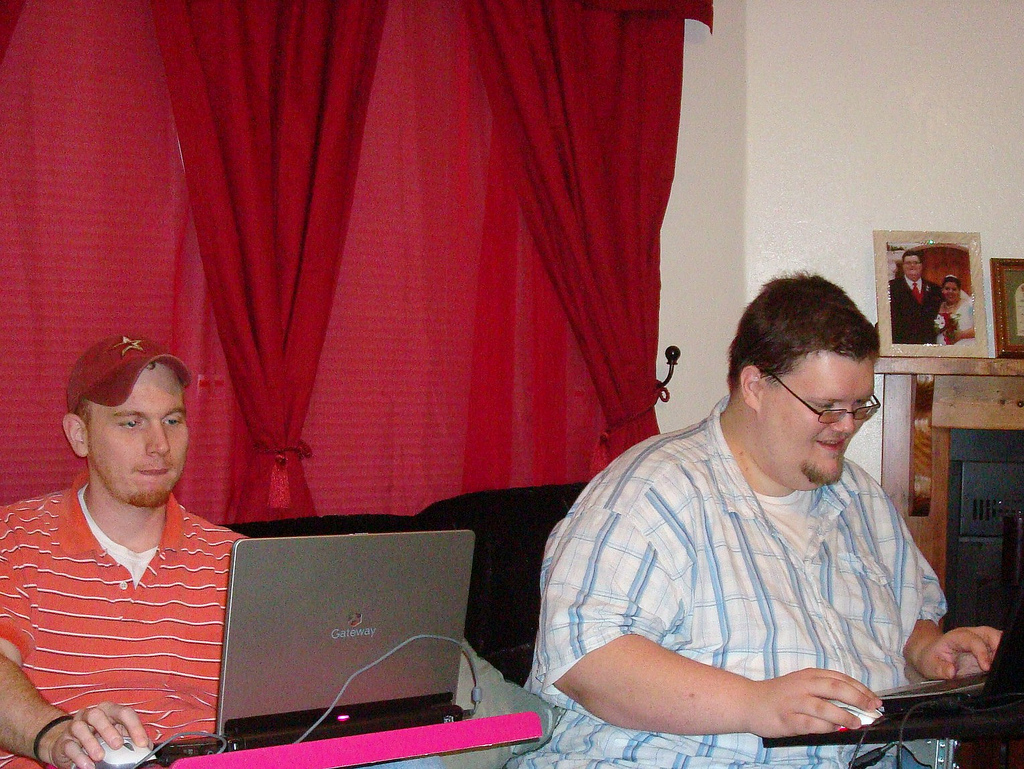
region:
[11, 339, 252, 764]
man is clicking his mouse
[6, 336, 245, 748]
man wearing orange shirt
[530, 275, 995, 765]
man wearing white and blue shirt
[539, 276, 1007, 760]
man typing on keyboard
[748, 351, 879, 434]
glasses are black in color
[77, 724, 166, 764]
laptop mouse is white and gray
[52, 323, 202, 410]
man wearing red hat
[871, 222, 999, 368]
picture has a white frame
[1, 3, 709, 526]
the curtains are red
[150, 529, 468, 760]
silver gateway laptop computer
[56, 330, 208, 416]
red hat with star logo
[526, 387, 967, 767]
white button with blue stripes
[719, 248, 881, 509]
man wearing reading glasses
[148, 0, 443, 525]
bright red window curtains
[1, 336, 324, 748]
man working on laptop computer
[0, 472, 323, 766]
orange polo with white stripes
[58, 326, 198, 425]
the red baseball hat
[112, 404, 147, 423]
the eyebrow of the face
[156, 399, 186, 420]
the eyebrow of the face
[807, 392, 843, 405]
the eyebrow of the face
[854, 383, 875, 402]
the eyebrow of the face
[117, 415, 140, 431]
the eye of the face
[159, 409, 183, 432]
the eye of the face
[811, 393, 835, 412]
the eye of the face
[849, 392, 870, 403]
the eye of the face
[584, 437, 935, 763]
man wearing a white shirt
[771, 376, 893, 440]
man wearing reading glasses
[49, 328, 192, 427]
man wearing a red hat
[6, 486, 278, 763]
man wearing a orange shirt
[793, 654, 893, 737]
man holding a mouse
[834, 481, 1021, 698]
Man using a laptop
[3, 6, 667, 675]
red curtain on the window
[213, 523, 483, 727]
large silver and black laptop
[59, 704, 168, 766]
hand holding computer mouse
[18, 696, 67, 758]
black band on wrist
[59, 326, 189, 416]
dark red baseball cap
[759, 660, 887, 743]
hand holding white computer mouse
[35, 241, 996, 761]
a pair of men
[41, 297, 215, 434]
a red baseball hat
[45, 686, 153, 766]
man holding a mouse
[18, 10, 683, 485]
a pair of curtains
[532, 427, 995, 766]
a white and blue shirt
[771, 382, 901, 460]
a pair of glasses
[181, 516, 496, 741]
a silver open laptop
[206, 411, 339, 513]
ties on the curtain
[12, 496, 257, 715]
a orange striped shirt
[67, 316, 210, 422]
a man wearing a red hat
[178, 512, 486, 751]
a silver laptop comptuer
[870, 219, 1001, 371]
a framed picture on a mantel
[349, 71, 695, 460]
red curtains covering a window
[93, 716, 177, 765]
a white computer mouse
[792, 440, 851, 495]
a man with a beard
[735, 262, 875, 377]
a man with red hair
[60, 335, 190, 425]
a man wearing a red hat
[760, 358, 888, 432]
a man wearing eye glasses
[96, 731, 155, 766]
a white computer mouse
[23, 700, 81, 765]
a man wearing a black wrist band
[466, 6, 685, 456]
red curtains covering a window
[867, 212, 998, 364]
a frame photo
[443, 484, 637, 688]
a black couch